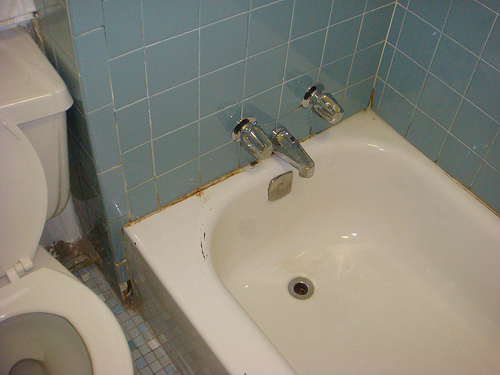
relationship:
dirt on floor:
[46, 231, 97, 276] [51, 237, 182, 369]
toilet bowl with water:
[0, 273, 125, 373] [9, 332, 74, 371]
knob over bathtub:
[231, 116, 273, 160] [122, 110, 497, 372]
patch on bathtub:
[268, 170, 290, 202] [122, 110, 497, 372]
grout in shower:
[175, 181, 211, 217] [218, 92, 343, 187]